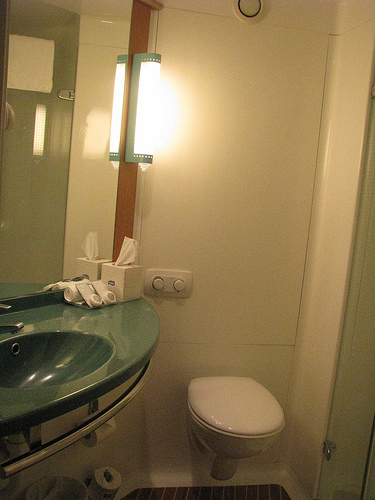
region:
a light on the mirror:
[121, 40, 173, 171]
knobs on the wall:
[143, 265, 201, 307]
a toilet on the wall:
[183, 360, 315, 492]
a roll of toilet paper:
[82, 459, 124, 495]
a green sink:
[2, 296, 156, 444]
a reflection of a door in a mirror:
[0, 1, 88, 259]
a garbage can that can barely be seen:
[29, 470, 85, 498]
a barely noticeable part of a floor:
[128, 480, 291, 496]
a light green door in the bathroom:
[318, 288, 373, 498]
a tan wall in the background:
[178, 41, 289, 258]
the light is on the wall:
[131, 46, 164, 193]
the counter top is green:
[51, 308, 114, 376]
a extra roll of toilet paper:
[85, 458, 142, 498]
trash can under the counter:
[19, 468, 88, 496]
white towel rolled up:
[62, 280, 105, 307]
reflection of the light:
[30, 103, 70, 163]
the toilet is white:
[191, 354, 280, 441]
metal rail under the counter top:
[8, 353, 180, 429]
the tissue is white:
[111, 242, 149, 276]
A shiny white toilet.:
[186, 374, 286, 481]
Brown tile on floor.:
[121, 483, 291, 498]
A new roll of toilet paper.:
[87, 465, 123, 498]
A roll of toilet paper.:
[75, 406, 118, 448]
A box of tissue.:
[100, 235, 142, 304]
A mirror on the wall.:
[1, 1, 132, 299]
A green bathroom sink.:
[1, 287, 160, 438]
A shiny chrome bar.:
[1, 357, 152, 478]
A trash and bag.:
[22, 471, 89, 498]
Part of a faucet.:
[0, 301, 25, 334]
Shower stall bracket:
[320, 436, 337, 461]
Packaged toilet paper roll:
[87, 462, 127, 496]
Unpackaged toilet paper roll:
[75, 409, 116, 442]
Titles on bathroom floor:
[154, 485, 208, 496]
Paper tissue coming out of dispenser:
[112, 232, 137, 262]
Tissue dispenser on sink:
[99, 256, 142, 304]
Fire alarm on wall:
[225, 0, 273, 27]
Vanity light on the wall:
[120, 48, 160, 165]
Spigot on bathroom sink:
[0, 316, 22, 333]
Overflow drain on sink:
[10, 339, 20, 355]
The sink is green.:
[40, 310, 117, 358]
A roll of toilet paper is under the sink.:
[75, 405, 130, 454]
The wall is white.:
[217, 205, 289, 305]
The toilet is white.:
[178, 367, 291, 492]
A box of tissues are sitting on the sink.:
[97, 227, 156, 314]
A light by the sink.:
[121, 42, 168, 180]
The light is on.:
[115, 42, 170, 178]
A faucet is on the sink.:
[0, 296, 28, 353]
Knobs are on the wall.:
[139, 259, 204, 305]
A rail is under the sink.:
[3, 327, 170, 481]